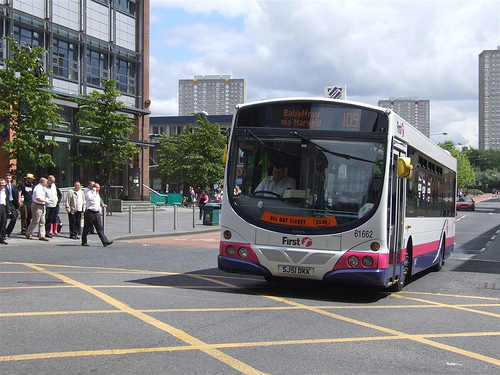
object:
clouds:
[143, 0, 499, 151]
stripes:
[331, 249, 390, 271]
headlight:
[368, 240, 380, 252]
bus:
[212, 95, 457, 292]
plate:
[278, 265, 315, 276]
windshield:
[224, 97, 389, 236]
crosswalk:
[0, 198, 224, 244]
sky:
[149, 0, 498, 150]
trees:
[65, 76, 142, 207]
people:
[79, 182, 114, 249]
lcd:
[235, 103, 378, 133]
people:
[63, 180, 86, 241]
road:
[0, 238, 499, 371]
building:
[175, 74, 247, 118]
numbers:
[367, 229, 373, 239]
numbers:
[352, 112, 360, 128]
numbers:
[353, 229, 359, 238]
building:
[0, 0, 152, 201]